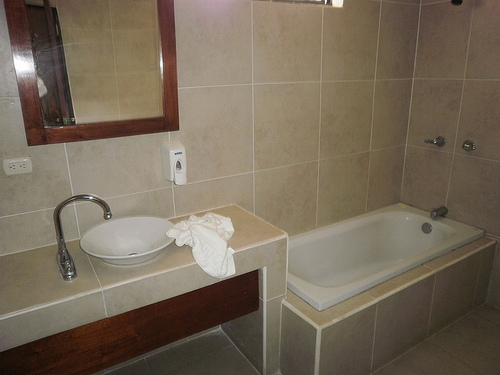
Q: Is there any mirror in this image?
A: Yes, there is a mirror.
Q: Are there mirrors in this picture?
A: Yes, there is a mirror.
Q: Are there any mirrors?
A: Yes, there is a mirror.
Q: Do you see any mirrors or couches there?
A: Yes, there is a mirror.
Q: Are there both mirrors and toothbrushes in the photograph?
A: No, there is a mirror but no toothbrushes.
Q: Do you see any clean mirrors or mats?
A: Yes, there is a clean mirror.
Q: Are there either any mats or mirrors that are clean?
A: Yes, the mirror is clean.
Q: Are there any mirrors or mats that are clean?
A: Yes, the mirror is clean.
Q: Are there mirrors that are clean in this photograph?
A: Yes, there is a clean mirror.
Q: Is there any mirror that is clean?
A: Yes, there is a mirror that is clean.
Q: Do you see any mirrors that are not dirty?
A: Yes, there is a clean mirror.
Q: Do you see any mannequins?
A: No, there are no mannequins.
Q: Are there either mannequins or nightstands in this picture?
A: No, there are no mannequins or nightstands.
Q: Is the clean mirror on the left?
A: Yes, the mirror is on the left of the image.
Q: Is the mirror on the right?
A: No, the mirror is on the left of the image.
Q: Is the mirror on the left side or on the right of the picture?
A: The mirror is on the left of the image.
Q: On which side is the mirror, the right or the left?
A: The mirror is on the left of the image.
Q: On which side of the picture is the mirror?
A: The mirror is on the left of the image.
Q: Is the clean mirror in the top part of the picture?
A: Yes, the mirror is in the top of the image.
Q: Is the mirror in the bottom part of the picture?
A: No, the mirror is in the top of the image.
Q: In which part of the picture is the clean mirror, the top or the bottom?
A: The mirror is in the top of the image.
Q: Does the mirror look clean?
A: Yes, the mirror is clean.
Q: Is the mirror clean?
A: Yes, the mirror is clean.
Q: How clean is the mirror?
A: The mirror is clean.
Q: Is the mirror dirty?
A: No, the mirror is clean.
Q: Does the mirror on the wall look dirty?
A: No, the mirror is clean.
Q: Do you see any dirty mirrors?
A: No, there is a mirror but it is clean.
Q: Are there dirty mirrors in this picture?
A: No, there is a mirror but it is clean.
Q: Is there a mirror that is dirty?
A: No, there is a mirror but it is clean.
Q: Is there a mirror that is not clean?
A: No, there is a mirror but it is clean.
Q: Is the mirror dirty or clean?
A: The mirror is clean.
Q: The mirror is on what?
A: The mirror is on the wall.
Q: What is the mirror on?
A: The mirror is on the wall.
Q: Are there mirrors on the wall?
A: Yes, there is a mirror on the wall.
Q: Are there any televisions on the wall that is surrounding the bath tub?
A: No, there is a mirror on the wall.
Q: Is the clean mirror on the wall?
A: Yes, the mirror is on the wall.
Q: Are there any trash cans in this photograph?
A: No, there are no trash cans.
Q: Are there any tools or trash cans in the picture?
A: No, there are no trash cans or tools.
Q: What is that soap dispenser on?
A: The soap dispenser is on the wall.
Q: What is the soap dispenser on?
A: The soap dispenser is on the wall.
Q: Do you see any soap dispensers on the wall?
A: Yes, there is a soap dispenser on the wall.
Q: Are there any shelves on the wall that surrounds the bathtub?
A: No, there is a soap dispenser on the wall.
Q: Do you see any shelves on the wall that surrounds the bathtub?
A: No, there is a soap dispenser on the wall.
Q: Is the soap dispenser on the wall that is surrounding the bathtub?
A: Yes, the soap dispenser is on the wall.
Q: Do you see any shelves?
A: No, there are no shelves.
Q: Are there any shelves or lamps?
A: No, there are no shelves or lamps.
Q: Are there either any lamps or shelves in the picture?
A: No, there are no shelves or lamps.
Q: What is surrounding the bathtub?
A: The wall is surrounding the bathtub.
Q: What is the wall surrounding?
A: The wall is surrounding the bathtub.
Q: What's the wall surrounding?
A: The wall is surrounding the bathtub.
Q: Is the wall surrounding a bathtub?
A: Yes, the wall is surrounding a bathtub.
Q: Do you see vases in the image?
A: No, there are no vases.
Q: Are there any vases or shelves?
A: No, there are no vases or shelves.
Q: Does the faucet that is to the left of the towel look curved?
A: Yes, the tap is curved.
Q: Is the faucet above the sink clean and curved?
A: Yes, the faucet is clean and curved.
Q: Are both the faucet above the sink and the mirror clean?
A: Yes, both the faucet and the mirror are clean.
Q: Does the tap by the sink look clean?
A: Yes, the tap is clean.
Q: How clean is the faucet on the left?
A: The tap is clean.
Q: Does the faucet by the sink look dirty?
A: No, the faucet is clean.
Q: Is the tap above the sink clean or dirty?
A: The faucet is clean.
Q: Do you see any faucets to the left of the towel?
A: Yes, there is a faucet to the left of the towel.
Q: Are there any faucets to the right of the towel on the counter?
A: No, the faucet is to the left of the towel.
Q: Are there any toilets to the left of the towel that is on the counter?
A: No, there is a faucet to the left of the towel.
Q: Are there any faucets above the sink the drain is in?
A: Yes, there is a faucet above the sink.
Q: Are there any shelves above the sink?
A: No, there is a faucet above the sink.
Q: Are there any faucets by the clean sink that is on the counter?
A: Yes, there is a faucet by the sink.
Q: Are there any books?
A: No, there are no books.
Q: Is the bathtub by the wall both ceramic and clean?
A: Yes, the bathtub is ceramic and clean.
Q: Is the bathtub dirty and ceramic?
A: No, the bathtub is ceramic but clean.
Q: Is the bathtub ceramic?
A: Yes, the bathtub is ceramic.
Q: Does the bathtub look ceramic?
A: Yes, the bathtub is ceramic.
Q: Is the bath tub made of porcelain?
A: Yes, the bath tub is made of porcelain.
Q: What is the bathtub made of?
A: The bath tub is made of porcelain.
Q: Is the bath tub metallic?
A: No, the bath tub is ceramic.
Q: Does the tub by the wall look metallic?
A: No, the tub is ceramic.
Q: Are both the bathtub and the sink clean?
A: Yes, both the bathtub and the sink are clean.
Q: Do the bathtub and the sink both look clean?
A: Yes, both the bathtub and the sink are clean.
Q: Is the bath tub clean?
A: Yes, the bath tub is clean.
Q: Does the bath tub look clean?
A: Yes, the bath tub is clean.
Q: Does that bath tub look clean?
A: Yes, the bath tub is clean.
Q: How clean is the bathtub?
A: The bathtub is clean.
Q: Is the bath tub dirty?
A: No, the bath tub is clean.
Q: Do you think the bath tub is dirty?
A: No, the bath tub is clean.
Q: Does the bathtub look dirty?
A: No, the bathtub is clean.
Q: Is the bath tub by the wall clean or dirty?
A: The bathtub is clean.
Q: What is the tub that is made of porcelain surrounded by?
A: The bathtub is surrounded by the wall.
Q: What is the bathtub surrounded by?
A: The bathtub is surrounded by the wall.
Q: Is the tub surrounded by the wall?
A: Yes, the tub is surrounded by the wall.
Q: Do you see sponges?
A: No, there are no sponges.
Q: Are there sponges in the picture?
A: No, there are no sponges.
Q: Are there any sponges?
A: No, there are no sponges.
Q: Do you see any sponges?
A: No, there are no sponges.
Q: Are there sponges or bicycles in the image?
A: No, there are no sponges or bicycles.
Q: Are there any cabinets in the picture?
A: No, there are no cabinets.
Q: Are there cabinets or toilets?
A: No, there are no cabinets or toilets.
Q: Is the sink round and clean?
A: Yes, the sink is round and clean.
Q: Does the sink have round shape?
A: Yes, the sink is round.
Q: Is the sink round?
A: Yes, the sink is round.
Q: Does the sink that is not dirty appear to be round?
A: Yes, the sink is round.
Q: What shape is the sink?
A: The sink is round.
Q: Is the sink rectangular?
A: No, the sink is round.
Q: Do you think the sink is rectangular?
A: No, the sink is round.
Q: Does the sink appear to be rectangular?
A: No, the sink is round.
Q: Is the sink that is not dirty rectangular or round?
A: The sink is round.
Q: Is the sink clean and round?
A: Yes, the sink is clean and round.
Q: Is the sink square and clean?
A: No, the sink is clean but round.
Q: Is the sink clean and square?
A: No, the sink is clean but round.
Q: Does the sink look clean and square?
A: No, the sink is clean but round.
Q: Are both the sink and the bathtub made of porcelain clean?
A: Yes, both the sink and the bathtub are clean.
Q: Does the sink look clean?
A: Yes, the sink is clean.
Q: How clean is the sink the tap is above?
A: The sink is clean.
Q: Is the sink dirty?
A: No, the sink is clean.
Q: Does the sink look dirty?
A: No, the sink is clean.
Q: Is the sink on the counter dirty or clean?
A: The sink is clean.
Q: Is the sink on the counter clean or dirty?
A: The sink is clean.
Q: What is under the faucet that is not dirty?
A: The sink is under the faucet.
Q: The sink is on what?
A: The sink is on the counter.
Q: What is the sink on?
A: The sink is on the counter.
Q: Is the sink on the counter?
A: Yes, the sink is on the counter.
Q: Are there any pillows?
A: No, there are no pillows.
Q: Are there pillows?
A: No, there are no pillows.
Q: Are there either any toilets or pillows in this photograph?
A: No, there are no pillows or toilets.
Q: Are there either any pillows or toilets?
A: No, there are no pillows or toilets.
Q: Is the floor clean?
A: Yes, the floor is clean.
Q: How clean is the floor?
A: The floor is clean.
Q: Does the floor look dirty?
A: No, the floor is clean.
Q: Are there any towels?
A: Yes, there is a towel.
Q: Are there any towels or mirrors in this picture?
A: Yes, there is a towel.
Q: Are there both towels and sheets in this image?
A: No, there is a towel but no sheets.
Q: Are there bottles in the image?
A: No, there are no bottles.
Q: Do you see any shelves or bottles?
A: No, there are no bottles or shelves.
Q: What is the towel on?
A: The towel is on the counter.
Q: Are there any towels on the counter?
A: Yes, there is a towel on the counter.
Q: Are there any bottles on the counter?
A: No, there is a towel on the counter.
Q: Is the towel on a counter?
A: Yes, the towel is on a counter.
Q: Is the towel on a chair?
A: No, the towel is on a counter.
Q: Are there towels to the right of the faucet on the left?
A: Yes, there is a towel to the right of the tap.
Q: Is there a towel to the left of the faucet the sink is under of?
A: No, the towel is to the right of the tap.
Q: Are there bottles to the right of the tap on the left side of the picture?
A: No, there is a towel to the right of the faucet.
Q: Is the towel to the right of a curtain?
A: No, the towel is to the right of a faucet.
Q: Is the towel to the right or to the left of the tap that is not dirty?
A: The towel is to the right of the faucet.